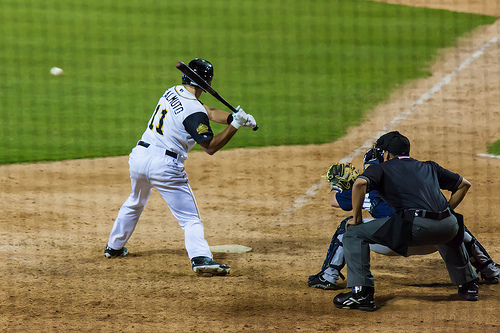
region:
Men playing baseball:
[101, 30, 498, 317]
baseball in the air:
[37, 45, 96, 96]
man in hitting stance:
[108, 41, 258, 283]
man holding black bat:
[171, 59, 258, 124]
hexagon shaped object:
[200, 220, 255, 258]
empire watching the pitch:
[334, 126, 494, 307]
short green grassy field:
[5, 3, 448, 56]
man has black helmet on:
[122, 35, 238, 97]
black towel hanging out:
[367, 207, 425, 265]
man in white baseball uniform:
[113, 60, 259, 292]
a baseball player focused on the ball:
[46, 23, 268, 306]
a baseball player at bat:
[86, 44, 283, 330]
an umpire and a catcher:
[306, 117, 483, 332]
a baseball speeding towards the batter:
[31, 51, 75, 85]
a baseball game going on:
[1, 1, 498, 328]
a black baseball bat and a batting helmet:
[172, 49, 292, 153]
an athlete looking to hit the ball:
[92, 40, 280, 285]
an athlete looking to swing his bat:
[91, 29, 283, 314]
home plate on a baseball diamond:
[197, 226, 267, 264]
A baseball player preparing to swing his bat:
[100, 49, 262, 278]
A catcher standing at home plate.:
[303, 119, 498, 317]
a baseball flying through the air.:
[41, 58, 69, 82]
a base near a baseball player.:
[196, 235, 273, 262]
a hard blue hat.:
[173, 53, 223, 90]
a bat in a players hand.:
[170, 57, 268, 132]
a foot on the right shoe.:
[179, 260, 231, 279]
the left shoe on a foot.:
[103, 236, 134, 261]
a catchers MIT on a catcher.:
[306, 159, 372, 222]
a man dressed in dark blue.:
[318, 119, 484, 309]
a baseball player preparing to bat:
[96, 38, 275, 297]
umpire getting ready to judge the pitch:
[328, 131, 491, 323]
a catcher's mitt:
[319, 155, 364, 194]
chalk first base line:
[381, 33, 498, 127]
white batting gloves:
[213, 102, 265, 136]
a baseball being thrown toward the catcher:
[43, 58, 70, 83]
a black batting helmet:
[171, 59, 221, 99]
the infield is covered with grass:
[1, 43, 448, 160]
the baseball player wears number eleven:
[93, 43, 268, 295]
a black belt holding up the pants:
[389, 207, 479, 229]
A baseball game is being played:
[1, 5, 492, 324]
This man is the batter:
[105, 56, 260, 276]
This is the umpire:
[331, 129, 479, 312]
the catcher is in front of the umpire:
[308, 147, 498, 288]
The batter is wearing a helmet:
[182, 55, 215, 94]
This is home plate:
[206, 236, 256, 256]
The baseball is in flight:
[49, 62, 64, 77]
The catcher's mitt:
[326, 160, 358, 192]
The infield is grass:
[0, 0, 345, 144]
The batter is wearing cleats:
[101, 245, 234, 279]